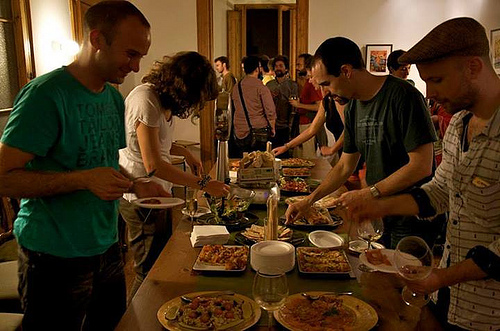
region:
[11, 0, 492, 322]
a group of people taking food.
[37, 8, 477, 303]
some people taking food.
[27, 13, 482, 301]
a group of people taking food at table.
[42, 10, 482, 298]
several people taking some food.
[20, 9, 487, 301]
a group of people serving themselves.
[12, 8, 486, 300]
several people serving themselves from table.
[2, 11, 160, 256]
a person wearing a green shirt.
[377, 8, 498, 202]
a person wearing a hat.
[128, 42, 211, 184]
a lady wearing white shirt.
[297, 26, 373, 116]
a person with dark colored hair.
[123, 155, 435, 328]
Table is filled with food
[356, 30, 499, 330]
Man is holding wine glass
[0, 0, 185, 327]
Man is wearing green shirt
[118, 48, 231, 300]
Woman has on white shirt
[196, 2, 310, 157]
People mingle in doorway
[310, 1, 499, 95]
Paintings hang on wall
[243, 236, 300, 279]
Plates are stacked on table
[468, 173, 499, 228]
Pack of cigarettes in pocket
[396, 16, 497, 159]
Man has a hat on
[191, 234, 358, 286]
The plates are square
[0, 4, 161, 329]
man wearing green shirt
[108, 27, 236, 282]
lady wearing white shirt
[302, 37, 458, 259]
man wearing green shirt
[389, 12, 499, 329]
man wearing cap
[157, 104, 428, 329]
food on table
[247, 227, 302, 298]
plates on table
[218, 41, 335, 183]
people standing in background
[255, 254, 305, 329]
wine glass on table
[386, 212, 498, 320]
man holding wine glass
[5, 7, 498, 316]
people dishing up food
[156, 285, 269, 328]
a large plate of food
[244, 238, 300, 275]
a stack of disposible plates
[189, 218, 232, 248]
a stack of paper napkins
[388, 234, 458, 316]
a big wine goblet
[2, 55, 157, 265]
the man has on a green shirt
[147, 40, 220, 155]
the lady's hair is curly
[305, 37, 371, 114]
the man has a mustache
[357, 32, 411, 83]
there is a colorful picture on the wall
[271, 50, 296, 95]
the man has a beard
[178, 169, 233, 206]
the lady is wearing a bracelet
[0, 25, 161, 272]
man in a green shirt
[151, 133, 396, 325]
buffet spread of food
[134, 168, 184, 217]
white plate in a man's hand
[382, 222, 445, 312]
empty wine glass in a man's hand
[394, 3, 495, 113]
brown cap on a man's head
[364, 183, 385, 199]
silver wrist watch on a man's wrist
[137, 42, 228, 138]
curly brown hair on a woman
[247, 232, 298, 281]
stack of white plates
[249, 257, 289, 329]
wine glass with some white wine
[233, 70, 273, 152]
black purse strap on a person's shoulder